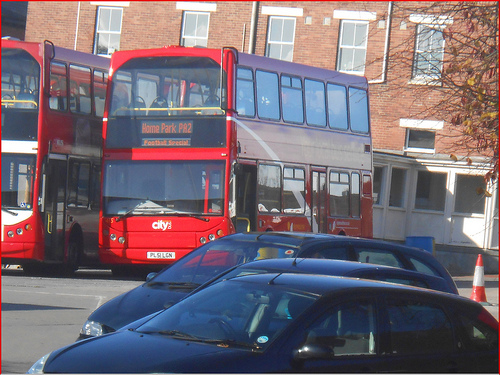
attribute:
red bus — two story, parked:
[92, 41, 374, 280]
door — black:
[42, 149, 72, 271]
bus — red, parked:
[0, 16, 110, 281]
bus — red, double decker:
[95, 42, 370, 272]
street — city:
[8, 235, 498, 324]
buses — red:
[70, 46, 416, 268]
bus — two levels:
[157, 40, 392, 203]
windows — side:
[237, 62, 368, 142]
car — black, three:
[27, 269, 494, 372]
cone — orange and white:
[469, 247, 491, 307]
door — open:
[234, 148, 263, 237]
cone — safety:
[469, 246, 485, 303]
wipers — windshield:
[140, 318, 277, 358]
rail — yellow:
[113, 96, 223, 118]